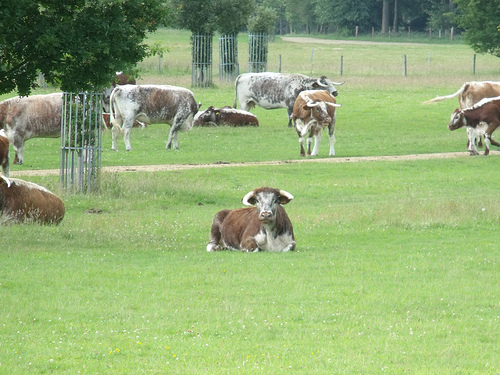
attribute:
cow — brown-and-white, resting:
[199, 105, 259, 127]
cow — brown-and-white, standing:
[1, 87, 78, 168]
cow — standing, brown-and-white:
[290, 89, 337, 159]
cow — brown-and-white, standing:
[233, 70, 345, 127]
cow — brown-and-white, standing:
[110, 83, 200, 150]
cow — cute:
[204, 184, 300, 259]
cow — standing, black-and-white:
[234, 55, 333, 135]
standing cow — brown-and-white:
[446, 101, 499, 150]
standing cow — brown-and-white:
[294, 83, 339, 160]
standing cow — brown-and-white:
[108, 80, 198, 155]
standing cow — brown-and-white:
[227, 61, 338, 133]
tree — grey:
[171, 0, 221, 87]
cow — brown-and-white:
[425, 81, 497, 107]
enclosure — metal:
[45, 83, 110, 189]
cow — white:
[230, 72, 340, 134]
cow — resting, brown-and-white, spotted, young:
[208, 183, 296, 255]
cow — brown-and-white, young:
[450, 98, 498, 153]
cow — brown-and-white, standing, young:
[293, 87, 342, 157]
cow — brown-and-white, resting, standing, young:
[0, 172, 65, 228]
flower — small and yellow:
[70, 344, 136, 366]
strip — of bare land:
[85, 148, 460, 180]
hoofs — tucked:
[250, 247, 289, 253]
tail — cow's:
[421, 81, 469, 103]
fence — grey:
[312, 50, 472, 128]